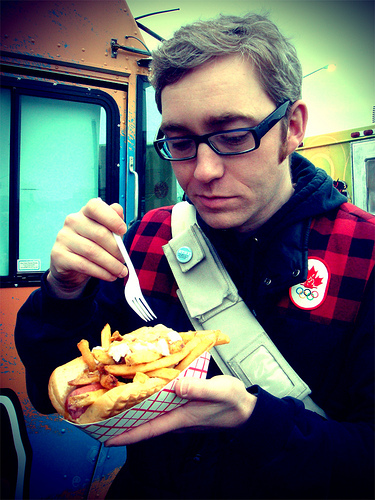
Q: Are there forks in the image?
A: Yes, there is a fork.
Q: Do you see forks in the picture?
A: Yes, there is a fork.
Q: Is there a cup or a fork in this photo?
A: Yes, there is a fork.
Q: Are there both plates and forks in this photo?
A: No, there is a fork but no plates.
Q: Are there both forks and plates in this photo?
A: No, there is a fork but no plates.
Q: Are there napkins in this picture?
A: No, there are no napkins.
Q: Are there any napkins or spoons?
A: No, there are no napkins or spoons.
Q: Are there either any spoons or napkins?
A: No, there are no napkins or spoons.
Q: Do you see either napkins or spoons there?
A: No, there are no napkins or spoons.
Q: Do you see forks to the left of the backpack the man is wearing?
A: Yes, there is a fork to the left of the backpack.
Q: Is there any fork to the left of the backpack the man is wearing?
A: Yes, there is a fork to the left of the backpack.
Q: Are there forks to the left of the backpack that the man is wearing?
A: Yes, there is a fork to the left of the backpack.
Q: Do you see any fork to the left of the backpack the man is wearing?
A: Yes, there is a fork to the left of the backpack.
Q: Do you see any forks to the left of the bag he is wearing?
A: Yes, there is a fork to the left of the backpack.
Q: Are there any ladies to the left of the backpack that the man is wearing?
A: No, there is a fork to the left of the backpack.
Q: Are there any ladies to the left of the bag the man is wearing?
A: No, there is a fork to the left of the backpack.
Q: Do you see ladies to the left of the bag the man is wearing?
A: No, there is a fork to the left of the backpack.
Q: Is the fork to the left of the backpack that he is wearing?
A: Yes, the fork is to the left of the backpack.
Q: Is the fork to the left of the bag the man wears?
A: Yes, the fork is to the left of the backpack.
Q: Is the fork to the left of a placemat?
A: No, the fork is to the left of the backpack.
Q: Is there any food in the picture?
A: Yes, there is food.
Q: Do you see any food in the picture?
A: Yes, there is food.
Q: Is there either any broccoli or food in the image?
A: Yes, there is food.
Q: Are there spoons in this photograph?
A: No, there are no spoons.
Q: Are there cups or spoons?
A: No, there are no spoons or cups.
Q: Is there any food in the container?
A: Yes, there is food in the container.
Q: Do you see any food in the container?
A: Yes, there is food in the container.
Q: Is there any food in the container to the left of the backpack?
A: Yes, there is food in the container.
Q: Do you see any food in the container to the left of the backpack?
A: Yes, there is food in the container.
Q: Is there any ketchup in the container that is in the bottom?
A: No, there is food in the container.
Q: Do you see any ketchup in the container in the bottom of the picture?
A: No, there is food in the container.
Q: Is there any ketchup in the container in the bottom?
A: No, there is food in the container.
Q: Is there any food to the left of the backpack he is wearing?
A: Yes, there is food to the left of the backpack.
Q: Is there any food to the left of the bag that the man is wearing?
A: Yes, there is food to the left of the backpack.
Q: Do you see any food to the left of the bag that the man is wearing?
A: Yes, there is food to the left of the backpack.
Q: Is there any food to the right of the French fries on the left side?
A: Yes, there is food to the right of the fries.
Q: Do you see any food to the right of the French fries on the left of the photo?
A: Yes, there is food to the right of the fries.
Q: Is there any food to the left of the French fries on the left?
A: No, the food is to the right of the French fries.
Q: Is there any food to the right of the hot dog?
A: Yes, there is food to the right of the hot dog.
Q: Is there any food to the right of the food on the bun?
A: Yes, there is food to the right of the hot dog.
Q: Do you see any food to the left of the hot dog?
A: No, the food is to the right of the hot dog.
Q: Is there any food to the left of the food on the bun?
A: No, the food is to the right of the hot dog.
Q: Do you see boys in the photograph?
A: No, there are no boys.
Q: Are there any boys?
A: No, there are no boys.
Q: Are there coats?
A: Yes, there is a coat.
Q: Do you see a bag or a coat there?
A: Yes, there is a coat.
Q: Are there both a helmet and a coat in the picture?
A: No, there is a coat but no helmets.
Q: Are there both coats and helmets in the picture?
A: No, there is a coat but no helmets.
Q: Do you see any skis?
A: No, there are no skis.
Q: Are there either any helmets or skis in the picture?
A: No, there are no skis or helmets.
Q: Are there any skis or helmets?
A: No, there are no skis or helmets.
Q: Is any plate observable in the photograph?
A: No, there are no plates.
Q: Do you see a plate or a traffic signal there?
A: No, there are no plates or traffic lights.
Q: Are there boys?
A: No, there are no boys.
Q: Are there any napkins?
A: No, there are no napkins.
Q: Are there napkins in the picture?
A: No, there are no napkins.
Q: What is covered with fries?
A: The bun is covered with fries.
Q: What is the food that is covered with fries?
A: The food is a bun.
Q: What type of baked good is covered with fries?
A: The food is a bun.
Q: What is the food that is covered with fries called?
A: The food is a bun.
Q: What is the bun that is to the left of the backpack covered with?
A: The bun is covered with fries.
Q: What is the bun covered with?
A: The bun is covered with fries.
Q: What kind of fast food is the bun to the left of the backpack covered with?
A: The bun is covered with fries.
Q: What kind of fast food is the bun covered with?
A: The bun is covered with fries.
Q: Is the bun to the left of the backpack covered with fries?
A: Yes, the bun is covered with fries.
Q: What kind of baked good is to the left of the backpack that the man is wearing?
A: The food is a bun.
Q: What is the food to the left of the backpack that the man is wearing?
A: The food is a bun.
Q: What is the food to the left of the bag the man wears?
A: The food is a bun.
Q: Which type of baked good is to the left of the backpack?
A: The food is a bun.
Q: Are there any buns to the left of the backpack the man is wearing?
A: Yes, there is a bun to the left of the backpack.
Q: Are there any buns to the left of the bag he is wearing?
A: Yes, there is a bun to the left of the backpack.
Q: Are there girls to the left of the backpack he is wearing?
A: No, there is a bun to the left of the backpack.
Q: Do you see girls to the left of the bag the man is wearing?
A: No, there is a bun to the left of the backpack.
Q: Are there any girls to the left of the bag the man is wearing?
A: No, there is a bun to the left of the backpack.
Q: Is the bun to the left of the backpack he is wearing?
A: Yes, the bun is to the left of the backpack.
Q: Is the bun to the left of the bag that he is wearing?
A: Yes, the bun is to the left of the backpack.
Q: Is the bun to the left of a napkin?
A: No, the bun is to the left of the backpack.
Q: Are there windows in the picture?
A: Yes, there is a window.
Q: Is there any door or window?
A: Yes, there is a window.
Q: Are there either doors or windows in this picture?
A: Yes, there is a window.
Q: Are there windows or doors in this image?
A: Yes, there is a window.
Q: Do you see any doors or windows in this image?
A: Yes, there is a window.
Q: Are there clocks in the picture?
A: No, there are no clocks.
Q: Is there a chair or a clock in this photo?
A: No, there are no clocks or chairs.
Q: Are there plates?
A: No, there are no plates.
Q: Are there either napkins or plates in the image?
A: No, there are no plates or napkins.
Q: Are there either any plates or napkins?
A: No, there are no plates or napkins.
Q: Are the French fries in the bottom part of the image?
A: Yes, the French fries are in the bottom of the image.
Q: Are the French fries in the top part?
A: No, the French fries are in the bottom of the image.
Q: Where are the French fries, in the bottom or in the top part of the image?
A: The French fries are in the bottom of the image.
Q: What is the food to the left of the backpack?
A: The food is fries.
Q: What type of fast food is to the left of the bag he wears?
A: The food is fries.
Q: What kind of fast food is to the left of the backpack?
A: The food is fries.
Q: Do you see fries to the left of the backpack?
A: Yes, there are fries to the left of the backpack.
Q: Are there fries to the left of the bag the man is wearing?
A: Yes, there are fries to the left of the backpack.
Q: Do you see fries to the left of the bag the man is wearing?
A: Yes, there are fries to the left of the backpack.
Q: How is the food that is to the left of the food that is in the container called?
A: The food is fries.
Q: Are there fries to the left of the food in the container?
A: Yes, there are fries to the left of the food.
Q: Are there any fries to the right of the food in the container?
A: No, the fries are to the left of the food.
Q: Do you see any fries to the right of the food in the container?
A: No, the fries are to the left of the food.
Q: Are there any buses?
A: Yes, there is a bus.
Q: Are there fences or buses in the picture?
A: Yes, there is a bus.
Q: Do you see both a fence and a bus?
A: No, there is a bus but no fences.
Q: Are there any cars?
A: No, there are no cars.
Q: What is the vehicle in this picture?
A: The vehicle is a bus.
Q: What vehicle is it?
A: The vehicle is a bus.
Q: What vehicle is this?
A: This is a bus.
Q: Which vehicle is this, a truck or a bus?
A: This is a bus.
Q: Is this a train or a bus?
A: This is a bus.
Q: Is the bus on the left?
A: Yes, the bus is on the left of the image.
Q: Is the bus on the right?
A: No, the bus is on the left of the image.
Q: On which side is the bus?
A: The bus is on the left of the image.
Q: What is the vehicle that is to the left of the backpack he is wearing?
A: The vehicle is a bus.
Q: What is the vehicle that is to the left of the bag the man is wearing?
A: The vehicle is a bus.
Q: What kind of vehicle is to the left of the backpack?
A: The vehicle is a bus.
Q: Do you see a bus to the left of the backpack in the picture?
A: Yes, there is a bus to the left of the backpack.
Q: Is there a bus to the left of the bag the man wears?
A: Yes, there is a bus to the left of the backpack.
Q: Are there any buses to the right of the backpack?
A: No, the bus is to the left of the backpack.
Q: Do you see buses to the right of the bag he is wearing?
A: No, the bus is to the left of the backpack.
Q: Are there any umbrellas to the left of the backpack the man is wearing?
A: No, there is a bus to the left of the backpack.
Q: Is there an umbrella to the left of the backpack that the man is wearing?
A: No, there is a bus to the left of the backpack.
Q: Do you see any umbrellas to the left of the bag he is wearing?
A: No, there is a bus to the left of the backpack.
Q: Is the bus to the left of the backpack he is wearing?
A: Yes, the bus is to the left of the backpack.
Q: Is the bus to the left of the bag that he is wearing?
A: Yes, the bus is to the left of the backpack.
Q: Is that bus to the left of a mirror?
A: No, the bus is to the left of the backpack.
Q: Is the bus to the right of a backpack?
A: No, the bus is to the left of a backpack.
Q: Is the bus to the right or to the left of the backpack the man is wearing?
A: The bus is to the left of the backpack.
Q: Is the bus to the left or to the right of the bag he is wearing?
A: The bus is to the left of the backpack.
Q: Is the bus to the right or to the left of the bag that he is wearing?
A: The bus is to the left of the backpack.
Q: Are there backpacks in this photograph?
A: Yes, there is a backpack.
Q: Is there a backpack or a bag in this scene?
A: Yes, there is a backpack.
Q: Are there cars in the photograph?
A: No, there are no cars.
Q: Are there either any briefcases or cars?
A: No, there are no cars or briefcases.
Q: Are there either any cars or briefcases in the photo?
A: No, there are no cars or briefcases.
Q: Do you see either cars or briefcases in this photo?
A: No, there are no cars or briefcases.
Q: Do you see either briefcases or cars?
A: No, there are no cars or briefcases.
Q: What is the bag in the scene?
A: The bag is a backpack.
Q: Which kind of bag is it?
A: The bag is a backpack.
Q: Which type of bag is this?
A: This is a backpack.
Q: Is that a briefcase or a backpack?
A: That is a backpack.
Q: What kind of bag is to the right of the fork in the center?
A: The bag is a backpack.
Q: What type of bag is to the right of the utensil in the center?
A: The bag is a backpack.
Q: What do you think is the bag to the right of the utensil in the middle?
A: The bag is a backpack.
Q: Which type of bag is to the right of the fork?
A: The bag is a backpack.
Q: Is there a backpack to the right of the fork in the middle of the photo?
A: Yes, there is a backpack to the right of the fork.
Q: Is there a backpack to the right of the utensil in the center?
A: Yes, there is a backpack to the right of the fork.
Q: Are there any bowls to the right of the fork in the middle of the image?
A: No, there is a backpack to the right of the fork.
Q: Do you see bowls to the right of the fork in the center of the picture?
A: No, there is a backpack to the right of the fork.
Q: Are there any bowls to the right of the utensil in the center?
A: No, there is a backpack to the right of the fork.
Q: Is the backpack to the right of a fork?
A: Yes, the backpack is to the right of a fork.